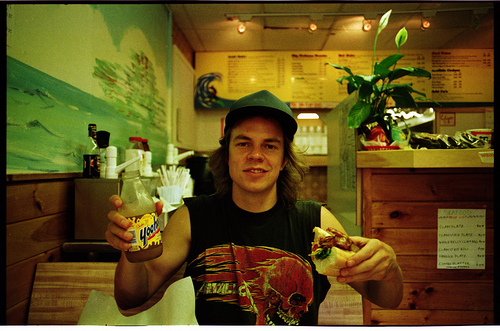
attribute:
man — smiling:
[155, 90, 381, 324]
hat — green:
[231, 91, 299, 128]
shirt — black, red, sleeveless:
[181, 193, 325, 330]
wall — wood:
[368, 171, 491, 329]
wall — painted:
[5, 6, 183, 184]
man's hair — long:
[205, 144, 233, 193]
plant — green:
[335, 20, 423, 143]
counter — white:
[355, 148, 499, 168]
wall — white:
[180, 53, 487, 173]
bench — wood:
[36, 267, 367, 316]